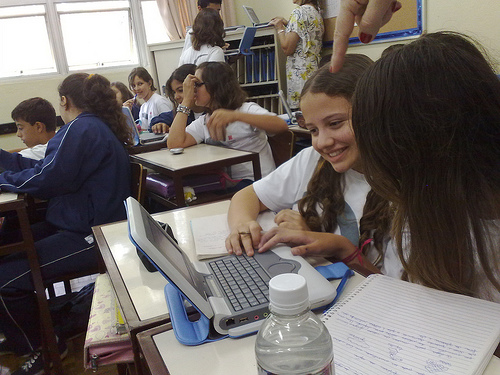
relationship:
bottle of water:
[255, 273, 340, 374] [255, 320, 338, 373]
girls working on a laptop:
[230, 50, 499, 307] [123, 195, 341, 338]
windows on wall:
[0, 1, 169, 79] [0, 4, 179, 125]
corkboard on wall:
[311, 0, 426, 54] [228, 2, 498, 79]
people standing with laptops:
[185, 1, 325, 94] [227, 0, 281, 58]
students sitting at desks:
[2, 54, 499, 314] [0, 145, 452, 375]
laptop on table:
[123, 195, 341, 338] [91, 196, 499, 372]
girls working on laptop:
[230, 50, 499, 307] [123, 195, 341, 338]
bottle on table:
[255, 273, 340, 374] [91, 196, 499, 372]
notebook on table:
[317, 272, 499, 374] [91, 196, 499, 372]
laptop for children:
[123, 195, 341, 338] [2, 54, 499, 314]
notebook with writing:
[317, 272, 499, 374] [331, 308, 475, 372]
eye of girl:
[329, 118, 342, 129] [224, 52, 416, 279]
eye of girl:
[307, 125, 317, 136] [224, 52, 416, 279]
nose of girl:
[314, 128, 335, 152] [224, 52, 416, 279]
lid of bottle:
[268, 272, 309, 313] [255, 273, 340, 374]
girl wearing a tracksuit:
[4, 68, 142, 374] [0, 115, 131, 356]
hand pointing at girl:
[327, 0, 403, 75] [225, 53, 395, 276]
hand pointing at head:
[327, 0, 403, 75] [299, 53, 373, 173]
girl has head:
[225, 53, 395, 276] [299, 53, 373, 173]